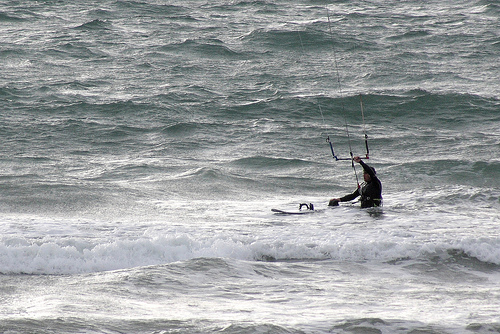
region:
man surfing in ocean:
[247, 81, 434, 243]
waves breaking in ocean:
[40, 201, 300, 301]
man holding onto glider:
[260, 68, 403, 253]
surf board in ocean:
[268, 187, 398, 226]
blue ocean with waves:
[16, 11, 261, 222]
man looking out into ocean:
[262, 121, 404, 232]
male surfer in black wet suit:
[277, 107, 416, 230]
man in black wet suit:
[338, 140, 388, 218]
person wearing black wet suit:
[326, 142, 405, 235]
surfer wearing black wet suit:
[255, 118, 412, 260]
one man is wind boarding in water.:
[238, 98, 398, 230]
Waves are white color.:
[21, 209, 278, 285]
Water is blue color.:
[56, 61, 211, 135]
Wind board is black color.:
[251, 168, 334, 231]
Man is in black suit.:
[333, 160, 393, 231]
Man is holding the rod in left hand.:
[326, 135, 386, 191]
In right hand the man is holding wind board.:
[278, 192, 357, 240]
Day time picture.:
[31, 20, 478, 308]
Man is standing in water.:
[301, 149, 390, 236]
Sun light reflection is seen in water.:
[48, 121, 268, 246]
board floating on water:
[272, 199, 331, 220]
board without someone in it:
[262, 193, 325, 213]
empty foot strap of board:
[300, 202, 314, 210]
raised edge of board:
[270, 205, 287, 217]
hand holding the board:
[328, 197, 343, 207]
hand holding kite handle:
[350, 149, 367, 162]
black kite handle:
[322, 140, 377, 165]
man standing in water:
[332, 149, 389, 210]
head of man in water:
[355, 168, 377, 180]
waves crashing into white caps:
[20, 203, 345, 275]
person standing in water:
[329, 152, 384, 209]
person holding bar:
[337, 155, 367, 162]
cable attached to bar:
[289, 0, 339, 159]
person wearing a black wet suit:
[339, 178, 383, 206]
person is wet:
[331, 155, 386, 209]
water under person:
[2, 1, 499, 332]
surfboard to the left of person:
[271, 200, 357, 213]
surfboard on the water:
[271, 202, 332, 214]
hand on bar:
[353, 154, 361, 161]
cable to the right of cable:
[320, 4, 355, 160]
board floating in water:
[269, 195, 329, 217]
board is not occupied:
[272, 196, 349, 217]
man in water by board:
[270, 163, 391, 217]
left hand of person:
[351, 151, 367, 163]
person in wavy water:
[332, 154, 392, 214]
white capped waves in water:
[20, 210, 468, 280]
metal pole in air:
[315, 125, 380, 165]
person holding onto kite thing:
[290, 10, 400, 220]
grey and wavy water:
[34, 28, 471, 183]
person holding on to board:
[247, 151, 392, 217]